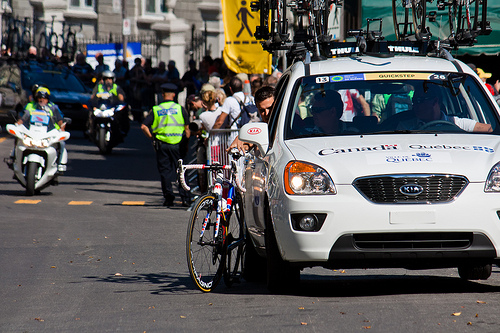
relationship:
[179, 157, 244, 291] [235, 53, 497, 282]
bike leaned against car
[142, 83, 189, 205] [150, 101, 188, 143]
man vest fluorescent yellow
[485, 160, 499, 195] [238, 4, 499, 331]
headlight on right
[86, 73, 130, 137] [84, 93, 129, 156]
cop on motorcycle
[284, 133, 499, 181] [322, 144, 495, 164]
hood has words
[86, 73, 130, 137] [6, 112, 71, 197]
cop on a motorcycle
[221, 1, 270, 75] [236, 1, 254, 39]
banner has a man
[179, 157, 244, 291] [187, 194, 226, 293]
bike has a tire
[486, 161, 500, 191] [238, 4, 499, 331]
light on right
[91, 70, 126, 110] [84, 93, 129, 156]
policeman on a motorcycle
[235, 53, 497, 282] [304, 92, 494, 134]
car has people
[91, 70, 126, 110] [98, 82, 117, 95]
policeman has a green vest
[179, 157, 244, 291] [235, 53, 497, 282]
bike leaned against th car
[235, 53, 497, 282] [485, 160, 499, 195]
car has headlight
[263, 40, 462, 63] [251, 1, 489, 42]
support carries bikes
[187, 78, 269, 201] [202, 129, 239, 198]
people are behind gate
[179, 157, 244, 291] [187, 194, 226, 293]
bike has tire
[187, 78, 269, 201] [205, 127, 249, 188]
people are behind a fence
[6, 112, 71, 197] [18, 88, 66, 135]
motorcycle have motorcyclists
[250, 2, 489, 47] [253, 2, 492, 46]
roof has bikes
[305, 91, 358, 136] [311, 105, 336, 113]
man has glasses